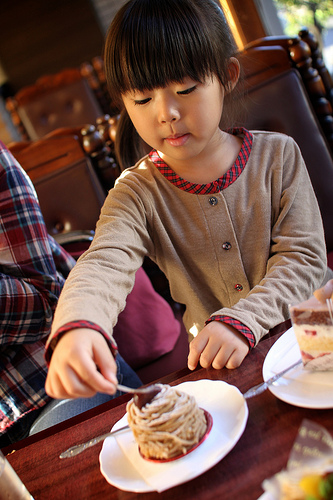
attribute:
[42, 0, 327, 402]
girl — little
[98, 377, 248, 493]
plate — white, round, small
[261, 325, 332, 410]
plate — white, small, round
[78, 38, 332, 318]
chair — grey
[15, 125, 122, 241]
chair — grey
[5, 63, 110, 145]
chair — grey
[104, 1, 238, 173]
hair — brown, straight, dark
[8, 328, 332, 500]
table — brown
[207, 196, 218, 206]
button — small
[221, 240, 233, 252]
button — small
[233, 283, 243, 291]
button — small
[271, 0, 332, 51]
tree — green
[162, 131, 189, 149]
lips — pursed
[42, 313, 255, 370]
cuffs — plaid, checkered, red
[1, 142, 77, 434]
shirt — plaid, red, blue checked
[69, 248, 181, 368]
purse — red, pink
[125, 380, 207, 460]
spaghetti — dessert, stacked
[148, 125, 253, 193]
collar — red, black plaid